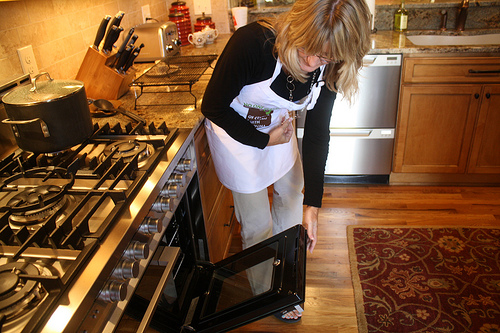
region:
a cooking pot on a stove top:
[0, 65, 97, 155]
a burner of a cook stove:
[96, 122, 163, 179]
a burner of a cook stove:
[1, 257, 49, 331]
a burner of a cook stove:
[0, 161, 76, 231]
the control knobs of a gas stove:
[101, 152, 198, 306]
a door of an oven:
[201, 219, 315, 328]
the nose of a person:
[305, 53, 320, 70]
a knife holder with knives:
[75, 7, 145, 99]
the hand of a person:
[268, 112, 303, 153]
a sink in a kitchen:
[406, 29, 498, 49]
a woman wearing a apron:
[186, 35, 356, 230]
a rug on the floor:
[345, 209, 476, 326]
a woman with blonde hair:
[278, 10, 363, 90]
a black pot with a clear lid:
[6, 62, 88, 169]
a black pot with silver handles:
[2, 68, 92, 165]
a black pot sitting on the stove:
[9, 74, 94, 159]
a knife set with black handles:
[87, 9, 143, 94]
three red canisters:
[167, 7, 222, 40]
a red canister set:
[157, 6, 214, 33]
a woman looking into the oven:
[171, 12, 373, 332]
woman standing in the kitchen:
[196, 2, 347, 327]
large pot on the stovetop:
[2, 75, 97, 160]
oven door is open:
[152, 195, 332, 325]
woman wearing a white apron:
[202, 2, 344, 322]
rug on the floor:
[341, 215, 496, 330]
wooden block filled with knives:
[70, 5, 150, 105]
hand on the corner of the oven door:
[280, 195, 320, 250]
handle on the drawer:
[457, 62, 497, 78]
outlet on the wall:
[11, 36, 53, 88]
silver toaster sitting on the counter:
[128, 20, 185, 61]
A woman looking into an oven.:
[12, 0, 486, 327]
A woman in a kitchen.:
[11, 5, 467, 315]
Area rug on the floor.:
[343, 215, 491, 332]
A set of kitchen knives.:
[78, 7, 145, 109]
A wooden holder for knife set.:
[71, 8, 144, 100]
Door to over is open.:
[182, 220, 317, 330]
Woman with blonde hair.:
[196, 4, 381, 214]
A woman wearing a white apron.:
[178, 8, 368, 213]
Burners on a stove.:
[1, 120, 151, 322]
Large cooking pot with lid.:
[1, 65, 92, 151]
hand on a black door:
[289, 203, 331, 255]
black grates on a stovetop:
[14, 187, 141, 244]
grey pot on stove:
[9, 65, 95, 155]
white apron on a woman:
[208, 40, 321, 198]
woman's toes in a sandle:
[275, 304, 315, 325]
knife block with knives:
[98, 25, 143, 105]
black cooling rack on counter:
[133, 48, 213, 100]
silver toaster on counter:
[122, 16, 188, 61]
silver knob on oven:
[103, 275, 132, 308]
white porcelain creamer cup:
[186, 20, 221, 53]